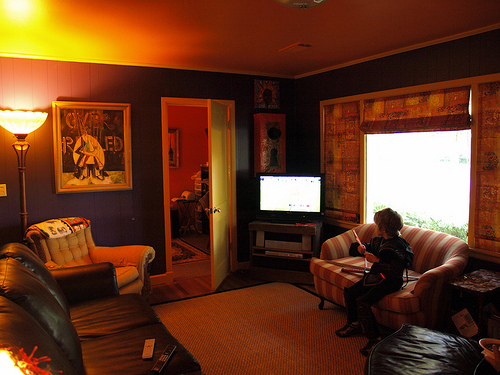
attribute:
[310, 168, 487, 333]
couch — big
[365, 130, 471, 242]
window — open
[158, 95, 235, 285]
door way — open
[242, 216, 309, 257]
stand — wooden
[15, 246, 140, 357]
brown hair — leather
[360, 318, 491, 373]
foot stool — black, leather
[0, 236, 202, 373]
leather sofa — black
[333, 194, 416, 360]
kid — seated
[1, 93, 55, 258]
floor lamp — turned on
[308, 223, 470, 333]
couch — striped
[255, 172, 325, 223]
tv — lcd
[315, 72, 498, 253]
curtains — decorative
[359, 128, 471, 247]
window — open, bright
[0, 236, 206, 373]
couch — big, brown